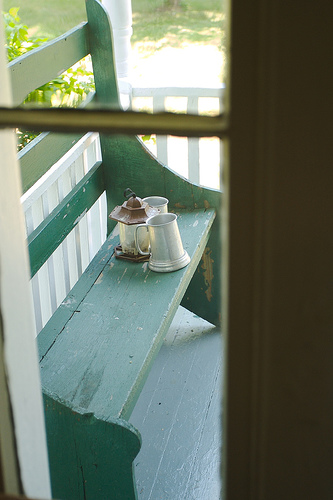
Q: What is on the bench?
A: Mugs.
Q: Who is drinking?
A: No one.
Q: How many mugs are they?
A: 2.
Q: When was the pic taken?
A: During the day.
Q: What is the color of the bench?
A: Green.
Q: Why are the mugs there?
A: Someone left them.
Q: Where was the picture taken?
A: A porch.